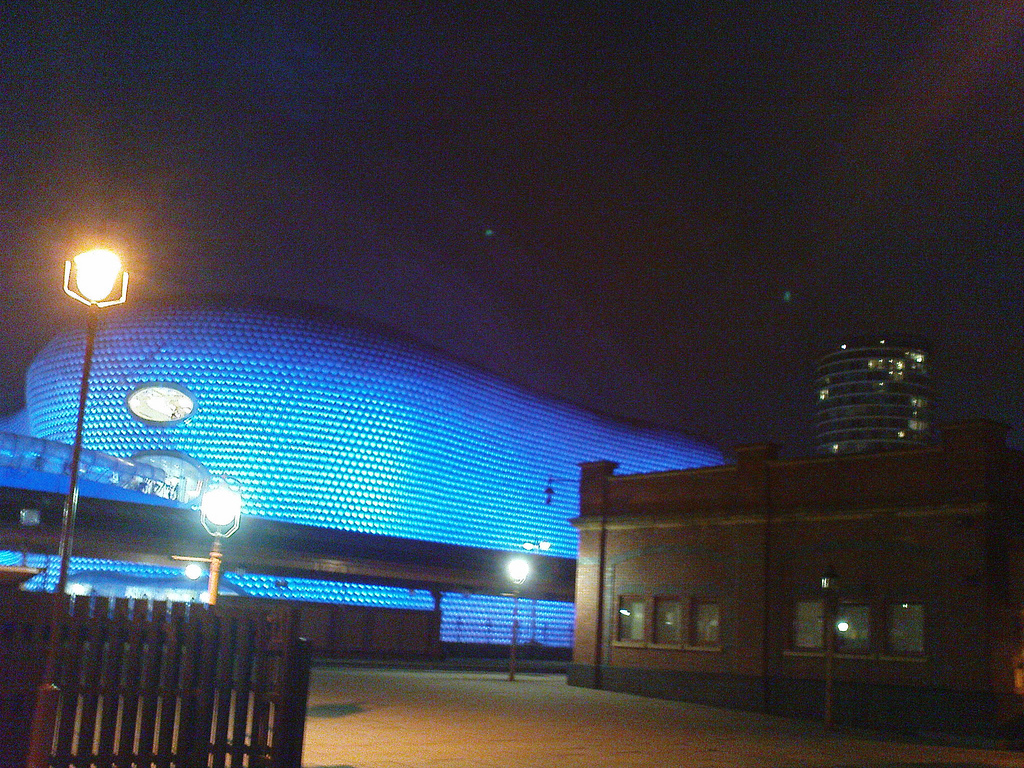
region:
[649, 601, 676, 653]
a window on a building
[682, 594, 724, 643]
a window on a building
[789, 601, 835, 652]
a window on a building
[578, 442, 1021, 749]
a building in a city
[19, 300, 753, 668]
a building in a city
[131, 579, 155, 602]
a window on a building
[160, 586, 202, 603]
a window on a building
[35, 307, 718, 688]
blue lit up building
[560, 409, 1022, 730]
building beside the blue building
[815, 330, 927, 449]
circular tall building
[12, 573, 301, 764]
picket fence on the sidewalk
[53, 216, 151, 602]
yellow light on the pole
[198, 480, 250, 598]
light on the yellow pole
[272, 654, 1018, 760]
pavement around the buildings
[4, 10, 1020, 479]
dark sky behind the buildings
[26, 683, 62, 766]
yellow cement post by the fence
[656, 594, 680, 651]
a window on a building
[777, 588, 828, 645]
a window on a building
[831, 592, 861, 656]
a window on a building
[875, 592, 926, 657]
a window on a building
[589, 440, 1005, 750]
a building in a city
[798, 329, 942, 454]
a building in a city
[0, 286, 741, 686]
a building in a city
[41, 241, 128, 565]
a light post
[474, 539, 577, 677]
Lamp post on corner.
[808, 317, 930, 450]
Tall building with some lights lit.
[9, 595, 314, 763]
Brown wooden fence.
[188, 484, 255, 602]
Bright light on post.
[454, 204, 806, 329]
Stars in the sky.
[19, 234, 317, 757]
Bright lights behind fence.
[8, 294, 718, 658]
Very large blue building.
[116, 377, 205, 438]
Oval light on blue building.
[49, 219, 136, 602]
A light near a fence.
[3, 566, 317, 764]
A fence near a light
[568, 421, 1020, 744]
A short brown building.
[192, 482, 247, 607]
A light on a sidewalk.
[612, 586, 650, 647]
A window on a building.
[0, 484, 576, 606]
A metal structure on a building.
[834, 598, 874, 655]
A window on a building.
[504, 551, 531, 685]
A light near a building.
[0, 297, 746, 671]
A large blue building.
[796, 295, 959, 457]
A building in the background with lights on.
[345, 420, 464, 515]
the building is blue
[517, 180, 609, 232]
the sky is dark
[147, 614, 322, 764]
fence on the ground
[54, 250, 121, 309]
light on the pole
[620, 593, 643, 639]
glass window on building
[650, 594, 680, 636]
glass window on building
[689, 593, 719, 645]
glass window on building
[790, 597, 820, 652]
glass window on building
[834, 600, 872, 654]
glass window on building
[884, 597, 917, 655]
glass window on building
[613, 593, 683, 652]
glass windows on building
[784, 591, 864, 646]
glass windows on building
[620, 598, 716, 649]
glass windows on building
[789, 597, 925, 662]
glass windows on building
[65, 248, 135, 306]
street light is turned on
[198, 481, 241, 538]
street light is turned on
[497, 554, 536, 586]
street light is turned on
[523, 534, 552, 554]
street light is turned on